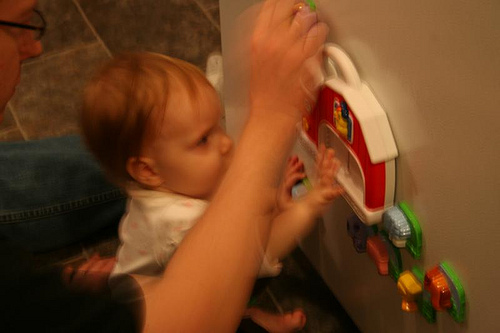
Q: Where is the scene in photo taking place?
A: In the kitchen.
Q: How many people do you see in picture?
A: 2.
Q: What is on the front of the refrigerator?
A: Child's magnetic farm set.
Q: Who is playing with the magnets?
A: Father and toddler.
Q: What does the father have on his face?
A: Glasses.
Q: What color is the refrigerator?
A: Almond.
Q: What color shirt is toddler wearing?
A: White.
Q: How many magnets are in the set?
A: 7.